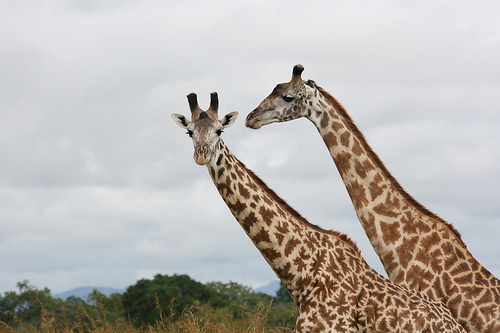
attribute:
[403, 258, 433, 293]
spot — brown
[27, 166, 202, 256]
clouds — white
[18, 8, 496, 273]
sky — blue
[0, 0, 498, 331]
sky — blue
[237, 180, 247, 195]
spot — brown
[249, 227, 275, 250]
spot — brown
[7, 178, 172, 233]
cloud — white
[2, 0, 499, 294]
clouds — white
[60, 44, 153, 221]
sky — blue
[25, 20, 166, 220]
cloud — white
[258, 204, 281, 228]
spot — brown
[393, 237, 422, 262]
spot — brown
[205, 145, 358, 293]
neck — long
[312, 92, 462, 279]
neck — long